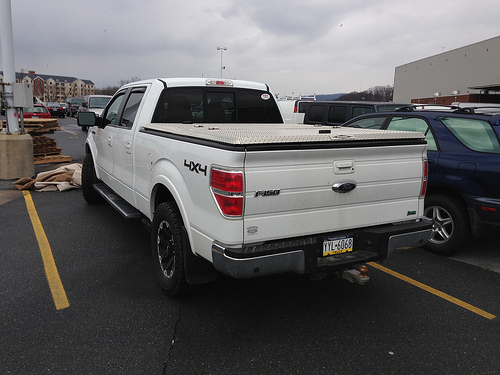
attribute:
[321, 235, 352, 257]
plate — license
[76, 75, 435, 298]
truck — 4 wheel drive, white, crew cab, silver, black, pickup, parked incorrectly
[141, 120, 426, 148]
cover — steel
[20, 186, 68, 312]
lines — yellow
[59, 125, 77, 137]
lines — yellow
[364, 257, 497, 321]
lines — yellow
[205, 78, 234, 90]
light — third, brake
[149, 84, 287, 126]
window — rear, tined, tinted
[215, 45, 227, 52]
lighting — outdoor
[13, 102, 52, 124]
car — red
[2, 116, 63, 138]
pallets — wooden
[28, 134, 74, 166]
pallets — wooden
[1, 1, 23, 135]
pole — grey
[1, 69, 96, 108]
complex — background, apartment, black, red, light brown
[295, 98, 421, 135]
van — black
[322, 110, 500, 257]
car — blue, black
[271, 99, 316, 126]
van — white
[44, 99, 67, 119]
car — black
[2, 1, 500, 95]
sky — cloudy, dreary